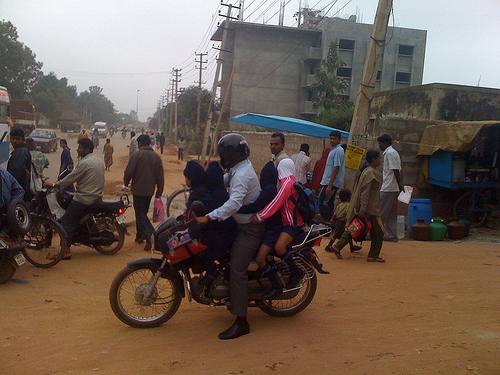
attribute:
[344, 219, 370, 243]
bag — red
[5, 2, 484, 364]
town — small 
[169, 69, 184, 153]
pole — for utilities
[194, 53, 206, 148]
pole — for utilities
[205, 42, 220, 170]
pole — for utilities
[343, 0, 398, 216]
pole — for utilities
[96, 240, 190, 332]
tire — front of motorcycle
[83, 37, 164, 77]
sky — blue sky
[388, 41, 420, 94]
buildings — tattered worn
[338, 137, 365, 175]
sign — yellow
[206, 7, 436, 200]
building — a concrete block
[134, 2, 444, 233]
eletrical poles — along the road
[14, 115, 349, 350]
people — on motorcycle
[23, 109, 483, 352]
street — made of dirt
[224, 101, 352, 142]
unbrella — blue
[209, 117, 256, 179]
man — wearing helmet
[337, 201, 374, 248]
trees — blue sky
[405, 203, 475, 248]
vases — on the ground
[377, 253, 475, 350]
ground — is dirt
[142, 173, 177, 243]
person — carrying a pink bag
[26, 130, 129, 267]
man — on the motorcycle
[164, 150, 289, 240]
people — riding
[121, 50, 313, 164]
poles — wood, electrical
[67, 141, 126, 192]
man — sitting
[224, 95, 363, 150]
canopy — blue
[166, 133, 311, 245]
family — four